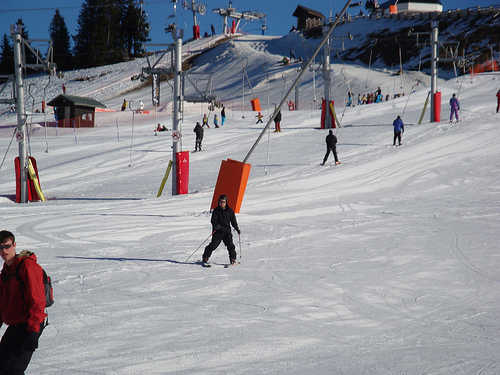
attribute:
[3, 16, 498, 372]
snow — white 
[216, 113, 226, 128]
pants — blue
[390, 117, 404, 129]
jacket — blue 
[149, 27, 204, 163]
post — metallic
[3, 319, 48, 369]
pants — black 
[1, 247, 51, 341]
jacket — red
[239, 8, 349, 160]
pole — white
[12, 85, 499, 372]
floor — grey 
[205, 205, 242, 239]
black coat — black 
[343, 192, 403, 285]
snow — white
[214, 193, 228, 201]
cap — black 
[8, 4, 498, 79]
sky — blue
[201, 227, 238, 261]
pants — black 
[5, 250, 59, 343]
jacket — red 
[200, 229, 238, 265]
pants — black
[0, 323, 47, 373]
pants — black